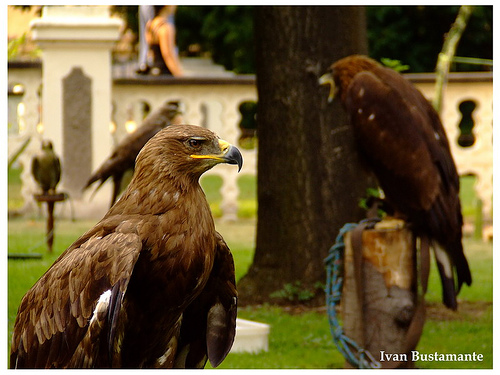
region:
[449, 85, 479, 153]
opening in far wall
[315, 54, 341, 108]
bird with its mouth open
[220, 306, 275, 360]
white structure behind bird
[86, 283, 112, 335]
white feather on bird's wing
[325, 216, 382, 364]
blue cord hanging over post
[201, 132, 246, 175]
a bird's yellow and black beak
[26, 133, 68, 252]
a bird in the distance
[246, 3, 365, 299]
a large tree trunk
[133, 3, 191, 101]
woman leaning against a low wall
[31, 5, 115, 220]
white pillar in the distance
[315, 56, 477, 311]
a brown bird of prey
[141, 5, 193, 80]
a woman walking by the birds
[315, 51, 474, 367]
bird tethered to a perch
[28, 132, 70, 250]
a parrot on a stand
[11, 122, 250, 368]
a brown falcon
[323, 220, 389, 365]
a blue woven cord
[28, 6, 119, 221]
a white and grey pillar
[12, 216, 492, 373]
lush green grass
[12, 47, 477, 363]
birds in a pen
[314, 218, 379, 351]
blue cord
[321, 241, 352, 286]
knots in blue cord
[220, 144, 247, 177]
blue beak on brown bird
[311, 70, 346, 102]
white mouth on brown bird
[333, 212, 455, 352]
large brown tree stump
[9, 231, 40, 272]
manicured green grass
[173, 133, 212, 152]
slanted black eye on bird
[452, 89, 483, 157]
beautiful architectural design on pink building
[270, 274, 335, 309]
small branches at bottom of tree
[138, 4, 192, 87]
girl wearing orange long sleeve shirt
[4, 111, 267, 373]
brown bird with black and yellow beak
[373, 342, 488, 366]
watermark that says Ivan Bustamante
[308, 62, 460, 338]
bird sitting on a stump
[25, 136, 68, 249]
bird sitting on a wooden stand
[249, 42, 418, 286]
tree trunk in the background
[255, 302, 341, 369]
grassy area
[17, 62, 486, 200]
wall in the background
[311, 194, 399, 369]
blue rope on a stump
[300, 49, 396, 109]
bird with an open beak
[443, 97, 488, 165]
opening in the wall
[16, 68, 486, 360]
Four birds outside.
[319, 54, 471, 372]
Bird on post with chain.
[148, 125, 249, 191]
Right profile of bird with sharp beak.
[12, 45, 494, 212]
Building with decorative cut-a-ways.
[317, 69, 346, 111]
Open beak on bird.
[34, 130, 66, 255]
Bird facing forward on perch.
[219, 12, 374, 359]
Tree with very large trunk.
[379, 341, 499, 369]
Name in right corner.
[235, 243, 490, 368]
Green grass around tree.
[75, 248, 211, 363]
White spot among brown feathers.